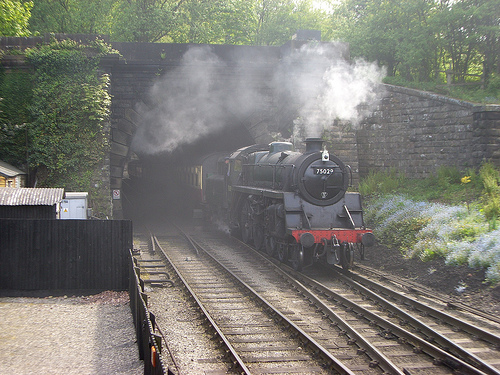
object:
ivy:
[0, 34, 128, 189]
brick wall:
[0, 33, 131, 218]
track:
[138, 222, 498, 375]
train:
[178, 136, 376, 274]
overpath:
[0, 36, 498, 222]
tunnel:
[120, 88, 276, 232]